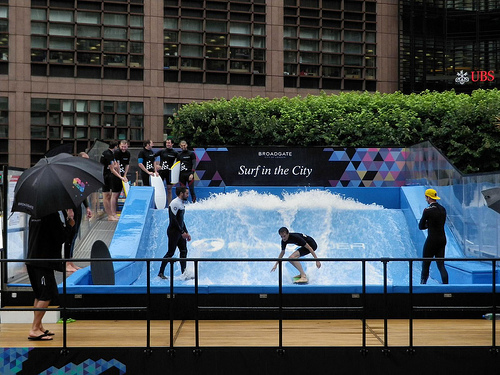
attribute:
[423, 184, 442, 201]
cap — yellow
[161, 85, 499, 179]
bushes — green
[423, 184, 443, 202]
hat — yellow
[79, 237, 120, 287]
board — black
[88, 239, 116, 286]
surfboard — black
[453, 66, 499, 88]
sign — UBS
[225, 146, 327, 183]
sign — black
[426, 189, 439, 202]
cap — yellow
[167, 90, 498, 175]
tree — tall, green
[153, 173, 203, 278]
wet suit — black, white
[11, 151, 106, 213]
umbrella — black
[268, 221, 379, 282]
wetsuit — black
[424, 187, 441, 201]
hat — black, yellow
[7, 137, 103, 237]
umbrella — black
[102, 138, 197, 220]
people — grouped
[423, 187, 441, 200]
cap — backwards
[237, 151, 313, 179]
lettering — white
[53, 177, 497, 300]
pool — artificial